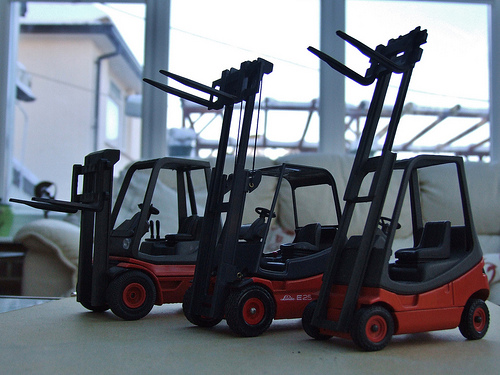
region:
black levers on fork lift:
[136, 65, 228, 107]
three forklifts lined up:
[41, 22, 460, 362]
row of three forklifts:
[3, 28, 484, 348]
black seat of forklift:
[393, 220, 448, 266]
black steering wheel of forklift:
[256, 197, 281, 221]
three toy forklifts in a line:
[8, 22, 484, 332]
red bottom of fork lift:
[358, 274, 480, 323]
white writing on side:
[283, 293, 318, 301]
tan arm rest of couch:
[11, 215, 86, 258]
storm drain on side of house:
[84, 40, 123, 98]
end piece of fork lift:
[301, 26, 378, 100]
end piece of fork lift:
[155, 59, 205, 113]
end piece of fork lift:
[35, 176, 77, 213]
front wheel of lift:
[127, 272, 155, 303]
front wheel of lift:
[220, 285, 282, 340]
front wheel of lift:
[364, 303, 402, 343]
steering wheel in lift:
[367, 211, 404, 236]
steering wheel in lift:
[254, 199, 282, 224]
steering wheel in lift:
[134, 192, 159, 220]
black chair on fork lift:
[412, 216, 456, 268]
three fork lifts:
[10, 18, 494, 360]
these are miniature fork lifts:
[16, 25, 498, 355]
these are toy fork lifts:
[12, 20, 497, 357]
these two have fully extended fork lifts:
[142, 18, 498, 372]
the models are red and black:
[30, 49, 497, 369]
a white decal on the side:
[247, 273, 337, 308]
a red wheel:
[228, 285, 281, 333]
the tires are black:
[337, 295, 403, 353]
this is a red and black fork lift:
[11, 126, 209, 334]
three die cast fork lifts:
[9, 13, 499, 354]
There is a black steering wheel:
[382, 207, 391, 220]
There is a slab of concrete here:
[231, 345, 241, 370]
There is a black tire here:
[368, 313, 380, 337]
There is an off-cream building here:
[64, 53, 70, 90]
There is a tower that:
[135, 36, 185, 131]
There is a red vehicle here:
[291, 283, 308, 335]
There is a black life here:
[336, 30, 363, 90]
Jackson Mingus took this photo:
[116, 31, 294, 369]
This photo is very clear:
[141, 75, 249, 365]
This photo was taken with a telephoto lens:
[124, 35, 285, 371]